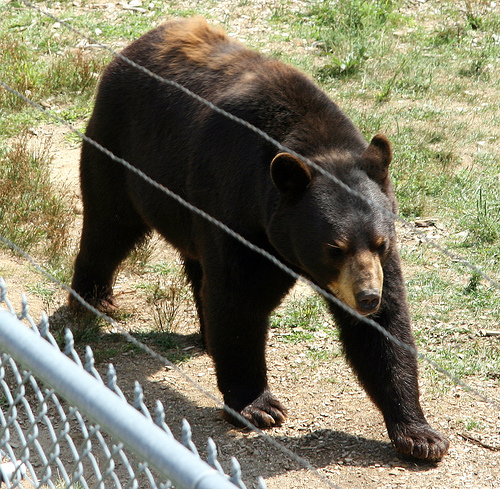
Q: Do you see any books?
A: No, there are no books.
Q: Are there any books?
A: No, there are no books.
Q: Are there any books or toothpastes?
A: No, there are no books or toothpastes.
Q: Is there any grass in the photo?
A: Yes, there is grass.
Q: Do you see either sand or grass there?
A: Yes, there is grass.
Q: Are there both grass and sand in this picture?
A: No, there is grass but no sand.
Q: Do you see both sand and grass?
A: No, there is grass but no sand.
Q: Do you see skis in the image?
A: No, there are no skis.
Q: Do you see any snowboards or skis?
A: No, there are no skis or snowboards.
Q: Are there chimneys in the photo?
A: No, there are no chimneys.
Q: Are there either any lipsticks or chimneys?
A: No, there are no chimneys or lipsticks.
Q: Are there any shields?
A: No, there are no shields.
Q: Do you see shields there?
A: No, there are no shields.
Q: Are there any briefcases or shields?
A: No, there are no shields or briefcases.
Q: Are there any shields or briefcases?
A: No, there are no shields or briefcases.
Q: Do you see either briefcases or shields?
A: No, there are no shields or briefcases.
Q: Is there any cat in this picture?
A: No, there are no cats.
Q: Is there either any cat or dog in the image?
A: No, there are no cats or dogs.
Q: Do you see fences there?
A: Yes, there is a fence.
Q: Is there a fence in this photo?
A: Yes, there is a fence.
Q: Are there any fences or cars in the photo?
A: Yes, there is a fence.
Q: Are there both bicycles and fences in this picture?
A: No, there is a fence but no bicycles.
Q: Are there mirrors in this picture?
A: No, there are no mirrors.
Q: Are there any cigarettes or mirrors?
A: No, there are no mirrors or cigarettes.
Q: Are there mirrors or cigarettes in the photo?
A: No, there are no mirrors or cigarettes.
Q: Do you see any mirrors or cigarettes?
A: No, there are no mirrors or cigarettes.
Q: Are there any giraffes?
A: No, there are no giraffes.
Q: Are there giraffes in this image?
A: No, there are no giraffes.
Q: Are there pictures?
A: No, there are no pictures.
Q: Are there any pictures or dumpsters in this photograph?
A: No, there are no pictures or dumpsters.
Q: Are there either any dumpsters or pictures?
A: No, there are no pictures or dumpsters.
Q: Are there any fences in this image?
A: Yes, there is a fence.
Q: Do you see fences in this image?
A: Yes, there is a fence.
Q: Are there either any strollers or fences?
A: Yes, there is a fence.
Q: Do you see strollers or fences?
A: Yes, there is a fence.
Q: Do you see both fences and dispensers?
A: No, there is a fence but no dispensers.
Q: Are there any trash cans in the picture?
A: No, there are no trash cans.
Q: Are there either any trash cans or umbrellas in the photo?
A: No, there are no trash cans or umbrellas.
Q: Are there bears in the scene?
A: Yes, there is a bear.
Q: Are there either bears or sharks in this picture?
A: Yes, there is a bear.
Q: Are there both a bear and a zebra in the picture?
A: No, there is a bear but no zebras.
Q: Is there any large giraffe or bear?
A: Yes, there is a large bear.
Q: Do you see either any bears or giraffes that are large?
A: Yes, the bear is large.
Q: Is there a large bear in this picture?
A: Yes, there is a large bear.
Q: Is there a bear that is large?
A: Yes, there is a bear that is large.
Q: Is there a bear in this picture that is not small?
A: Yes, there is a large bear.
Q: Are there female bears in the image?
A: Yes, there is a female bear.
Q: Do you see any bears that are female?
A: Yes, there is a female bear.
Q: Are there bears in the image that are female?
A: Yes, there is a bear that is female.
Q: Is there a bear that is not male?
A: Yes, there is a female bear.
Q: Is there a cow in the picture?
A: No, there are no cows.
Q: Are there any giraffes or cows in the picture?
A: No, there are no cows or giraffes.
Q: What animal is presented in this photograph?
A: The animal is a bear.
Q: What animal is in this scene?
A: The animal is a bear.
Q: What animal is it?
A: The animal is a bear.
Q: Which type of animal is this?
A: This is a bear.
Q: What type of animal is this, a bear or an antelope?
A: This is a bear.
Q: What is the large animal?
A: The animal is a bear.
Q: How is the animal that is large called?
A: The animal is a bear.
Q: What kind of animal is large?
A: The animal is a bear.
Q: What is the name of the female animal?
A: The animal is a bear.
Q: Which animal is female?
A: The animal is a bear.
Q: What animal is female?
A: The animal is a bear.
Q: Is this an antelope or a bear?
A: This is a bear.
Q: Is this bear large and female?
A: Yes, the bear is large and female.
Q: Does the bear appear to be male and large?
A: No, the bear is large but female.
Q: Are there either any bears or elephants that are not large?
A: No, there is a bear but she is large.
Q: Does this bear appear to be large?
A: Yes, the bear is large.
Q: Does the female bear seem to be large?
A: Yes, the bear is large.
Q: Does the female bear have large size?
A: Yes, the bear is large.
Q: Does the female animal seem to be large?
A: Yes, the bear is large.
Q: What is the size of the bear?
A: The bear is large.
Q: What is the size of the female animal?
A: The bear is large.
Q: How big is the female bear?
A: The bear is large.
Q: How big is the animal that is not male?
A: The bear is large.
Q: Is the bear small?
A: No, the bear is large.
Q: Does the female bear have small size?
A: No, the bear is large.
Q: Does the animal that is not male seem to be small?
A: No, the bear is large.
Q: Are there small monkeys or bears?
A: No, there is a bear but she is large.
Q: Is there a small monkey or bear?
A: No, there is a bear but she is large.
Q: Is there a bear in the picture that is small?
A: No, there is a bear but she is large.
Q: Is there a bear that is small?
A: No, there is a bear but she is large.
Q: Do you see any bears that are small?
A: No, there is a bear but she is large.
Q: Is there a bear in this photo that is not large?
A: No, there is a bear but she is large.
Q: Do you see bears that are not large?
A: No, there is a bear but she is large.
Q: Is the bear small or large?
A: The bear is large.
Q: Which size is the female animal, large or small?
A: The bear is large.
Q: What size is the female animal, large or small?
A: The bear is large.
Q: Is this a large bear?
A: Yes, this is a large bear.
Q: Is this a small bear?
A: No, this is a large bear.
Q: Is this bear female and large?
A: Yes, the bear is female and large.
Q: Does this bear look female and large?
A: Yes, the bear is female and large.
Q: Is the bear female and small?
A: No, the bear is female but large.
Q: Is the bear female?
A: Yes, the bear is female.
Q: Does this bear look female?
A: Yes, the bear is female.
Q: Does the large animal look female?
A: Yes, the bear is female.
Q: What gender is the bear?
A: The bear is female.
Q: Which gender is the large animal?
A: The bear is female.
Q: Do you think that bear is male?
A: No, the bear is female.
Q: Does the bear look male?
A: No, the bear is female.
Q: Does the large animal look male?
A: No, the bear is female.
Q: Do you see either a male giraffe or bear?
A: No, there is a bear but she is female.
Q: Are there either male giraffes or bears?
A: No, there is a bear but she is female.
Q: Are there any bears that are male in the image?
A: No, there is a bear but she is female.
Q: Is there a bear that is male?
A: No, there is a bear but she is female.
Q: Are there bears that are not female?
A: No, there is a bear but she is female.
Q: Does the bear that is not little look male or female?
A: The bear is female.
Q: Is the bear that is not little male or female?
A: The bear is female.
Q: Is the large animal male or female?
A: The bear is female.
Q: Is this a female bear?
A: Yes, this is a female bear.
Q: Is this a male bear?
A: No, this is a female bear.